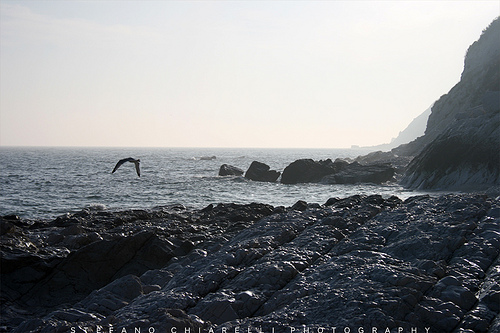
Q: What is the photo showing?
A: It is showing a beach.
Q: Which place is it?
A: It is a beach.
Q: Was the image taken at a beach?
A: Yes, it was taken in a beach.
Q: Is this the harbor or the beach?
A: It is the beach.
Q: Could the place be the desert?
A: No, it is the beach.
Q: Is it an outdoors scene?
A: Yes, it is outdoors.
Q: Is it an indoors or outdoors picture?
A: It is outdoors.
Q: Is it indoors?
A: No, it is outdoors.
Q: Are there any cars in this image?
A: No, there are no cars.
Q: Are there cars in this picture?
A: No, there are no cars.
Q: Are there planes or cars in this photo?
A: No, there are no cars or planes.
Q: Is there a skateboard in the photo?
A: No, there are no skateboards.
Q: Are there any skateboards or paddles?
A: No, there are no skateboards or paddles.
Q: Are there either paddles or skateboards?
A: No, there are no skateboards or paddles.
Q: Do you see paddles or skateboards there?
A: No, there are no skateboards or paddles.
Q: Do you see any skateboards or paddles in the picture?
A: No, there are no skateboards or paddles.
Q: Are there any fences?
A: No, there are no fences.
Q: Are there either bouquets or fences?
A: No, there are no fences or bouquets.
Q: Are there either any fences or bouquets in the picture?
A: No, there are no fences or bouquets.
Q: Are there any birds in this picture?
A: Yes, there is a bird.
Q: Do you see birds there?
A: Yes, there is a bird.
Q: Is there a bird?
A: Yes, there is a bird.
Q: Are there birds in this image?
A: Yes, there is a bird.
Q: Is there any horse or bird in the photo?
A: Yes, there is a bird.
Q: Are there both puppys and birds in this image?
A: No, there is a bird but no puppys.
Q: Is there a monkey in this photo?
A: No, there are no monkeys.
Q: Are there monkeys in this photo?
A: No, there are no monkeys.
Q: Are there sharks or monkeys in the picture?
A: No, there are no monkeys or sharks.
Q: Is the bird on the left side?
A: Yes, the bird is on the left of the image.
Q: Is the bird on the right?
A: No, the bird is on the left of the image.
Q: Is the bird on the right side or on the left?
A: The bird is on the left of the image.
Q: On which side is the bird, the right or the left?
A: The bird is on the left of the image.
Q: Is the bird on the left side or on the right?
A: The bird is on the left of the image.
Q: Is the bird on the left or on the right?
A: The bird is on the left of the image.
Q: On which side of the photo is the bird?
A: The bird is on the left of the image.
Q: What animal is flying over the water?
A: The bird is flying over the water.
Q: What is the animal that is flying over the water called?
A: The animal is a bird.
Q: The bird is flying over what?
A: The bird is flying over the water.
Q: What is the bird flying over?
A: The bird is flying over the water.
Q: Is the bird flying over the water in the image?
A: Yes, the bird is flying over the water.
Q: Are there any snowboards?
A: No, there are no snowboards.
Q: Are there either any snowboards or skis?
A: No, there are no snowboards or skis.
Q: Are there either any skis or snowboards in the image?
A: No, there are no snowboards or skis.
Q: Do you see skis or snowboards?
A: No, there are no snowboards or skis.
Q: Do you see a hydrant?
A: No, there are no fire hydrants.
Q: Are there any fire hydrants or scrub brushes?
A: No, there are no fire hydrants or scrub brushes.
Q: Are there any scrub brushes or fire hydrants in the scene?
A: No, there are no fire hydrants or scrub brushes.